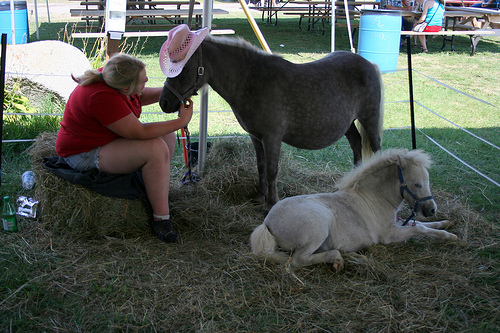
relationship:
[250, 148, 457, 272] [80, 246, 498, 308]
animal lying in grass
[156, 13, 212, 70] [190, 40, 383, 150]
hat on horse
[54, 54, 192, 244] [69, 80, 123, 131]
lady wearing red shirt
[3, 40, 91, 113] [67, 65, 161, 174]
boulder behind lady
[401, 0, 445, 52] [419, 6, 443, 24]
woman wearing blue shirt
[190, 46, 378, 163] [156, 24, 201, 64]
animal wearing hat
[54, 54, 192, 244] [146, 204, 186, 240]
lady has foot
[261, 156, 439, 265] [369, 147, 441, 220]
animal has head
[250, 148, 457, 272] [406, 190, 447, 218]
animal has nose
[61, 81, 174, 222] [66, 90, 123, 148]
lady wearing red shirt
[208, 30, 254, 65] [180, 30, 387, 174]
hair on animal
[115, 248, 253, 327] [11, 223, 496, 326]
hay on ground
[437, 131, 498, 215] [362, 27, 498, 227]
shadow on ground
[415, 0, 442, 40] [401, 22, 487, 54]
woman sitting on bench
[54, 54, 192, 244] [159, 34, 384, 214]
lady sitting next to animal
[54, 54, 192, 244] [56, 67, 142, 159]
lady wearing a red shirt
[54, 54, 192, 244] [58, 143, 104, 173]
lady wearing shorts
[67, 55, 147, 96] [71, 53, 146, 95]
hair in a hair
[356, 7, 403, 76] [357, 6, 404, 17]
trashcan with bag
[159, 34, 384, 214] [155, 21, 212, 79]
animal wearing hat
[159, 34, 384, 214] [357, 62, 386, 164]
animal with tail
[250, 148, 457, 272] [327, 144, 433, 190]
animal with mane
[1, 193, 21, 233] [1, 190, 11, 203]
bottle with top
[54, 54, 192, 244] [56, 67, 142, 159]
lady wearing red shirt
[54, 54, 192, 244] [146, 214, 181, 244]
lady wearing shoes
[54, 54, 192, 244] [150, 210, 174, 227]
lady wearing socks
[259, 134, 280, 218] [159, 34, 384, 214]
leg of a animal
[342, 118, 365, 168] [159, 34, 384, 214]
leg of a animal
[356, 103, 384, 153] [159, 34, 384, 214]
leg of a animal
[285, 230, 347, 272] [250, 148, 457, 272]
leg of a animal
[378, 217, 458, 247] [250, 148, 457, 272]
leg of a animal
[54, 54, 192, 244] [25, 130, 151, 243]
lady sitting on hay